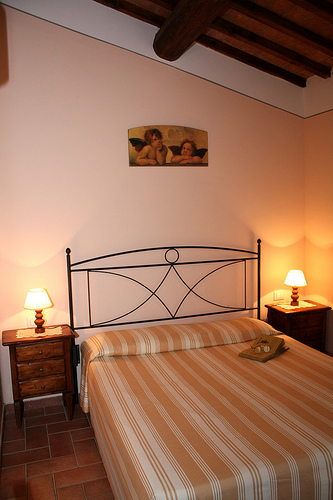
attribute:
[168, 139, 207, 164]
angel — small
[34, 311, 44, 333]
frame — brown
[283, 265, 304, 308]
light — illuminating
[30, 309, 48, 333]
base — wooden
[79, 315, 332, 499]
bedspread — orange, white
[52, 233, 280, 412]
bed frame — black, metal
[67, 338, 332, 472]
bedspread — brown, plaid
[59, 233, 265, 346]
frame — black, metal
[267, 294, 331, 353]
table — small, brown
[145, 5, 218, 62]
beam — exposed, wood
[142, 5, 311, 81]
beam — exposed, wood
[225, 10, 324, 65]
beam — exposed, wood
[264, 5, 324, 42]
beam — exposed, wood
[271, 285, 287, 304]
wall outlet — white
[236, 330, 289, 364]
towels — brown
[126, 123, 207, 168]
picture — small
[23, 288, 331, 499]
sheets — brown, white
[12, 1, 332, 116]
border — white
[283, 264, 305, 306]
lamp — small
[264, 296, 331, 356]
table — small, wooden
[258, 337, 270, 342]
letters — black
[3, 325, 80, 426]
table — brown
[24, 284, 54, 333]
lamp — small